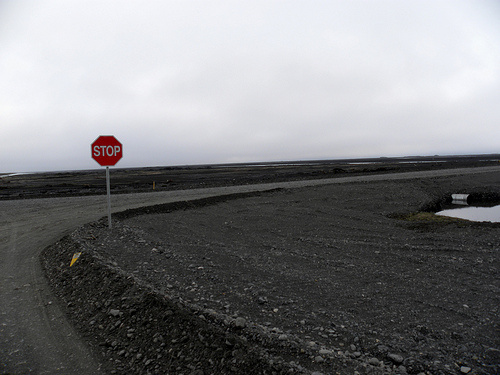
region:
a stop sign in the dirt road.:
[80, 128, 129, 244]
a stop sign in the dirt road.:
[82, 128, 132, 240]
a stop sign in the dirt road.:
[82, 132, 128, 239]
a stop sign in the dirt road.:
[87, 131, 130, 232]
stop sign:
[85, 132, 131, 165]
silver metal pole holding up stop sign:
[102, 165, 116, 227]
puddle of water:
[428, 195, 498, 226]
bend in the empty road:
[1, 189, 91, 257]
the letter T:
[98, 143, 110, 159]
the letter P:
[113, 143, 121, 159]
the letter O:
[105, 143, 117, 158]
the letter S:
[92, 143, 104, 156]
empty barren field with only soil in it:
[56, 178, 498, 369]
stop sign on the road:
[83, 132, 133, 241]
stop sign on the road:
[73, 129, 138, 249]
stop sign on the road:
[63, 130, 138, 235]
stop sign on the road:
[73, 128, 158, 248]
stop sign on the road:
[66, 126, 150, 244]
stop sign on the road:
[77, 131, 144, 256]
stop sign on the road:
[69, 125, 145, 245]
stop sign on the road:
[80, 129, 139, 251]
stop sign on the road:
[80, 133, 140, 248]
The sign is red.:
[89, 130, 124, 165]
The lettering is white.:
[89, 138, 121, 163]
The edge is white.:
[78, 126, 124, 171]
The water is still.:
[425, 187, 497, 228]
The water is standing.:
[430, 191, 490, 229]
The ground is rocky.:
[86, 188, 496, 373]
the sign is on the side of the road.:
[82, 129, 143, 244]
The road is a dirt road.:
[13, 137, 296, 373]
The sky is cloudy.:
[3, 5, 493, 171]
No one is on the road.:
[20, 131, 498, 364]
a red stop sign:
[79, 126, 131, 172]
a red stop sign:
[75, 131, 140, 185]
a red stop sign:
[75, 115, 145, 192]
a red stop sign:
[83, 116, 154, 181]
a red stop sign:
[64, 116, 142, 169]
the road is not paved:
[112, 202, 300, 342]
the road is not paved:
[172, 243, 328, 345]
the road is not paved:
[170, 258, 335, 369]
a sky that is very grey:
[114, 33, 454, 147]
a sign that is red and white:
[80, 129, 137, 176]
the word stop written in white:
[87, 139, 117, 159]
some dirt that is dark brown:
[161, 208, 375, 329]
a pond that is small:
[428, 183, 496, 237]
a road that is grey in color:
[10, 239, 91, 369]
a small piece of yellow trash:
[64, 246, 94, 268]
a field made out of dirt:
[24, 163, 384, 198]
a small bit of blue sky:
[1, 5, 22, 29]